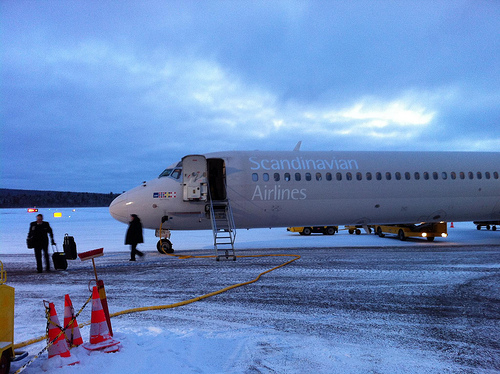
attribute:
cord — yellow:
[19, 227, 317, 367]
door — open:
[174, 115, 234, 211]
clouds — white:
[40, 52, 372, 136]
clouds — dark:
[17, 99, 65, 161]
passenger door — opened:
[176, 150, 207, 203]